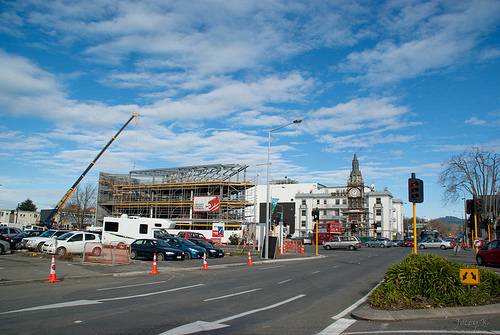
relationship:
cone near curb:
[44, 250, 66, 286] [0, 271, 105, 297]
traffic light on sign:
[412, 179, 419, 186] [402, 172, 429, 207]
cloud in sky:
[87, 33, 212, 56] [0, 0, 496, 130]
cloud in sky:
[463, 115, 488, 126] [0, 0, 496, 130]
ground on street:
[398, 141, 454, 188] [0, 243, 500, 335]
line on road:
[203, 287, 264, 301] [3, 245, 495, 333]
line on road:
[307, 270, 320, 277] [3, 245, 495, 333]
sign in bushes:
[457, 262, 477, 287] [365, 252, 499, 308]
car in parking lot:
[40, 231, 102, 254] [2, 222, 241, 267]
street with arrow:
[206, 234, 403, 331] [139, 293, 316, 333]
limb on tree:
[453, 180, 470, 185] [438, 149, 498, 244]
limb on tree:
[492, 154, 498, 177] [438, 149, 498, 244]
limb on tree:
[473, 147, 490, 167] [438, 149, 498, 244]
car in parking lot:
[40, 231, 102, 254] [3, 250, 255, 280]